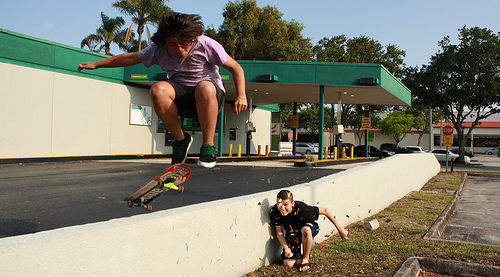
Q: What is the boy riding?
A: Skateboard.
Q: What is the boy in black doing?
A: Ducking down by wall.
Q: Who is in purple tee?
A: A man.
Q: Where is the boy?
A: Behind wall.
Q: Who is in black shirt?
A: A boy.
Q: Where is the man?
A: In air.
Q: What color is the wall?
A: White.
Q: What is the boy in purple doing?
A: Skateboarding.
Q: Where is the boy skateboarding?
A: On the wall.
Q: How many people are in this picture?
A: Two.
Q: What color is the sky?
A: Blue.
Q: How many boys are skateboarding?
A: One.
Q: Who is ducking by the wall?
A: The boy in the black shirt.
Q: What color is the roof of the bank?
A: Green.